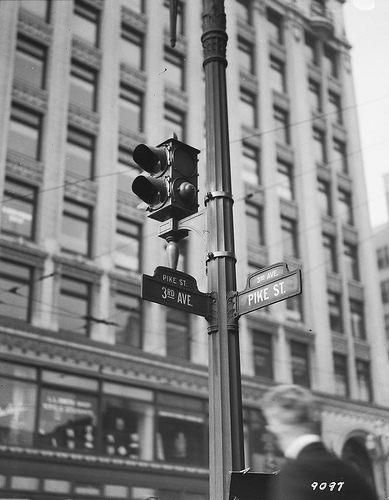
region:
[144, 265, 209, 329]
street sign on street post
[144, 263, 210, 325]
the sign says pike st 3rd ave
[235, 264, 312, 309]
the sign on the other side says 3rd Ave pike street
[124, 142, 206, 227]
street light above the street sign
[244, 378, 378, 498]
the man is waiting to cross the street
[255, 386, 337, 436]
the man has gray hair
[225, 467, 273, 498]
he has a brief case in his possession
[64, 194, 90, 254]
window on the high rise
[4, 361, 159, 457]
store front on the 2nd level of the building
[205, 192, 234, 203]
metal ring around the pole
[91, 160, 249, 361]
a post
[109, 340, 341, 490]
a post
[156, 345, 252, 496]
a post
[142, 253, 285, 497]
a post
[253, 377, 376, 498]
Man in a suit with very short hair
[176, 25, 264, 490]
Tall metal pole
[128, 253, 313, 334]
Two street signs on a pole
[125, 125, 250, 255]
Old stoplight attached to a pole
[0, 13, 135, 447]
Tall city building with many windows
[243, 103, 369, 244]
Wires up in the air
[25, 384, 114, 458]
Words in a window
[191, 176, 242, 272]
Brackets on a pole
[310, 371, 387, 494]
Arched entrance to a city building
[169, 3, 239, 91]
Design on a metal pole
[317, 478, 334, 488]
number 9097 is written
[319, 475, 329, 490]
number 9097 is written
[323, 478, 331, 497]
number 9097 is written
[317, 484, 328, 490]
number 9097 is written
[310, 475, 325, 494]
number 9097 is written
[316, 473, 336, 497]
number 9097 is written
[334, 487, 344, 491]
number 9097 is written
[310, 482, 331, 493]
number 9097 is written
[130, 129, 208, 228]
Traffic light in the center of the photo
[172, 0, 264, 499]
Street pole in the center of the photo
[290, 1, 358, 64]
Balcony in the far right corner of the pic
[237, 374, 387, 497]
Back of man's head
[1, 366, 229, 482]
Storefront displays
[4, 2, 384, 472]
Highrise building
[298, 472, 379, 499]
Number 9097 marking the photo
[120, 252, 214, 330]
Street sign for 3rd ave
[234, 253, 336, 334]
Street sign for Pike St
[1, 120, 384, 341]
Power and or telephone lines